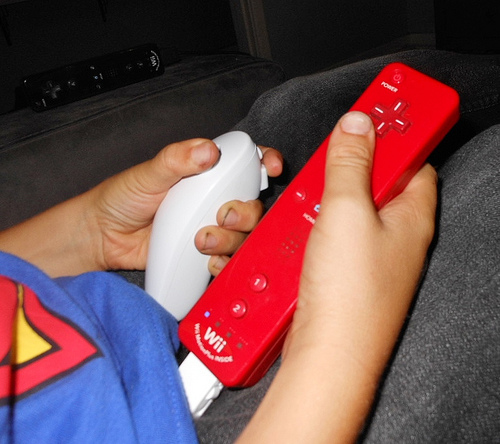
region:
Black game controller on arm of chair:
[32, 43, 171, 110]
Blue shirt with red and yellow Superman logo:
[0, 277, 108, 399]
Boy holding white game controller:
[142, 136, 257, 296]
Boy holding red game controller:
[295, 77, 435, 235]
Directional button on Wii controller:
[370, 95, 410, 132]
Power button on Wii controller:
[380, 67, 406, 93]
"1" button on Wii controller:
[250, 267, 270, 291]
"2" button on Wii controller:
[227, 295, 247, 317]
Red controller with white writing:
[192, 320, 232, 363]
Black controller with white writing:
[143, 45, 164, 71]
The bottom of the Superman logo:
[0, 272, 105, 408]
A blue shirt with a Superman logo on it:
[0, 253, 193, 441]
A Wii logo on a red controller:
[192, 323, 237, 360]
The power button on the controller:
[384, 70, 406, 91]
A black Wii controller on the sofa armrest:
[16, 44, 176, 110]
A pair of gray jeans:
[96, 50, 499, 442]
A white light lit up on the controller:
[198, 309, 213, 318]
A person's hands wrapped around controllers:
[8, 115, 438, 442]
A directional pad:
[369, 97, 408, 134]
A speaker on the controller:
[266, 217, 317, 256]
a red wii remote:
[170, 75, 457, 397]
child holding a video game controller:
[167, 133, 258, 298]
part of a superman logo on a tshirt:
[0, 280, 133, 417]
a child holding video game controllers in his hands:
[134, 61, 463, 403]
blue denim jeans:
[439, 316, 499, 403]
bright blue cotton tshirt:
[113, 322, 158, 392]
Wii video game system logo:
[189, 316, 237, 365]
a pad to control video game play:
[367, 86, 417, 140]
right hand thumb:
[332, 99, 376, 219]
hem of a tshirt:
[162, 387, 190, 437]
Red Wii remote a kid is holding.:
[177, 64, 461, 389]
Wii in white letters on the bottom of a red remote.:
[204, 325, 226, 352]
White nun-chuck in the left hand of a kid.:
[146, 130, 269, 330]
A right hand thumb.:
[318, 109, 378, 229]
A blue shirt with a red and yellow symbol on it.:
[2, 247, 200, 442]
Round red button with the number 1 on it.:
[251, 270, 268, 292]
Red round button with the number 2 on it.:
[229, 298, 248, 317]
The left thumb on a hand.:
[128, 139, 218, 187]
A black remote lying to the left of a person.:
[21, 45, 166, 111]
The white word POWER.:
[378, 79, 400, 93]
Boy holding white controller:
[145, 125, 276, 307]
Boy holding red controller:
[307, 65, 441, 274]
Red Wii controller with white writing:
[188, 323, 235, 366]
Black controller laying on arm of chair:
[27, 42, 167, 115]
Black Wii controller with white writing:
[145, 49, 160, 72]